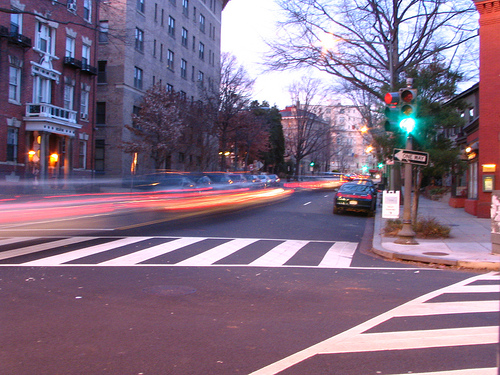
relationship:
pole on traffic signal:
[397, 137, 416, 243] [382, 88, 427, 148]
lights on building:
[360, 120, 379, 159] [294, 97, 379, 178]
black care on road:
[330, 180, 376, 216] [1, 188, 497, 373]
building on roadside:
[93, 1, 226, 176] [1, 190, 498, 373]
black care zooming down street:
[330, 180, 376, 216] [53, 215, 368, 373]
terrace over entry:
[34, 69, 92, 126] [42, 133, 71, 167]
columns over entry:
[28, 75, 44, 104] [42, 133, 71, 167]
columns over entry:
[41, 75, 53, 110] [42, 133, 71, 167]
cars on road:
[2, 176, 324, 264] [1, 188, 497, 373]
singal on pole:
[376, 102, 441, 165] [366, 86, 438, 246]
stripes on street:
[6, 238, 387, 280] [3, 161, 473, 373]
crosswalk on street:
[7, 222, 499, 274] [3, 161, 473, 373]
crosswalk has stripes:
[7, 222, 499, 274] [6, 238, 387, 280]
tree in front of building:
[122, 82, 189, 171] [107, 0, 222, 96]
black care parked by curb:
[330, 180, 376, 216] [372, 170, 499, 266]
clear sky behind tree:
[218, 1, 483, 103] [257, 0, 480, 202]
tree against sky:
[257, 0, 480, 202] [220, 0, 479, 108]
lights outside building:
[24, 149, 64, 171] [3, 20, 98, 163]